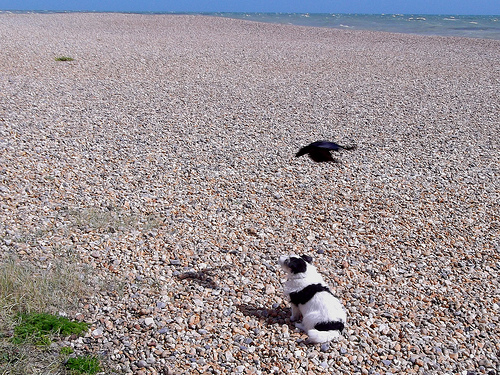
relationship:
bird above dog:
[296, 138, 357, 164] [278, 253, 348, 344]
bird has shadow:
[296, 138, 357, 164] [175, 262, 234, 290]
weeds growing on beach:
[0, 262, 123, 375] [0, 9, 500, 374]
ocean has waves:
[0, 7, 499, 38] [211, 11, 500, 31]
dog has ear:
[278, 253, 348, 344] [289, 256, 307, 272]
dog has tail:
[278, 253, 348, 344] [306, 326, 340, 344]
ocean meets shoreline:
[0, 7, 499, 38] [0, 11, 499, 41]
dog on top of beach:
[278, 253, 348, 344] [0, 9, 500, 374]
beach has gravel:
[0, 9, 500, 374] [1, 13, 500, 374]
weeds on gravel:
[0, 262, 123, 375] [1, 13, 500, 374]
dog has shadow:
[278, 253, 348, 344] [232, 302, 299, 330]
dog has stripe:
[278, 253, 348, 344] [288, 283, 341, 308]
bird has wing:
[296, 138, 357, 164] [308, 145, 338, 163]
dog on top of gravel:
[278, 253, 348, 344] [1, 13, 500, 374]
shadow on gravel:
[175, 262, 234, 290] [1, 13, 500, 374]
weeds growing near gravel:
[0, 262, 123, 375] [1, 13, 500, 374]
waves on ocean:
[211, 11, 500, 31] [0, 7, 499, 38]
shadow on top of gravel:
[232, 302, 299, 330] [1, 13, 500, 374]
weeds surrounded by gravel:
[0, 262, 123, 375] [1, 13, 500, 374]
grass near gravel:
[13, 310, 92, 346] [1, 13, 500, 374]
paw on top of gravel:
[288, 313, 299, 320] [1, 13, 500, 374]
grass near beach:
[13, 310, 92, 346] [0, 9, 500, 374]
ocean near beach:
[0, 7, 499, 38] [0, 9, 500, 374]